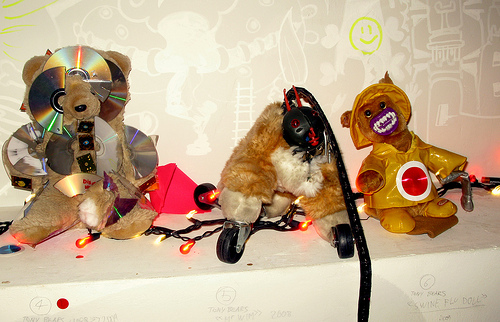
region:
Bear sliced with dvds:
[4, 50, 160, 242]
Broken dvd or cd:
[51, 170, 107, 197]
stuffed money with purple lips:
[341, 59, 478, 256]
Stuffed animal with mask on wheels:
[204, 79, 351, 276]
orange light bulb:
[178, 226, 199, 258]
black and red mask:
[278, 83, 329, 167]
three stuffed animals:
[12, 38, 487, 278]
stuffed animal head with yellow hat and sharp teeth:
[331, 67, 429, 149]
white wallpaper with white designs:
[148, 7, 347, 82]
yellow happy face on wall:
[346, 18, 393, 58]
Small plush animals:
[19, 38, 470, 255]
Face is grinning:
[360, 85, 405, 145]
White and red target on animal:
[396, 152, 434, 208]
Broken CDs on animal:
[38, 48, 161, 179]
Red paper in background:
[150, 160, 202, 220]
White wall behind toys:
[22, 10, 498, 93]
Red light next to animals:
[163, 220, 201, 260]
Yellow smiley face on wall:
[346, 12, 402, 64]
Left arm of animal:
[351, 159, 392, 203]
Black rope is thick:
[290, 76, 390, 315]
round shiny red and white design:
[391, 164, 430, 201]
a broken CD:
[18, 65, 79, 135]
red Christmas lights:
[76, 207, 343, 274]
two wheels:
[211, 202, 358, 269]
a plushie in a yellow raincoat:
[340, 80, 480, 241]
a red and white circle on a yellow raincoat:
[386, 160, 440, 204]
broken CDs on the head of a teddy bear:
[23, 46, 135, 132]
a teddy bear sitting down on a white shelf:
[9, 47, 178, 249]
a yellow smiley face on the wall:
[327, 12, 398, 62]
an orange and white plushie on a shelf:
[221, 95, 353, 234]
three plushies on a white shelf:
[12, 52, 489, 264]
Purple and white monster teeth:
[367, 108, 404, 138]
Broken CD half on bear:
[24, 65, 69, 135]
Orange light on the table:
[176, 234, 200, 256]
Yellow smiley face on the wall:
[339, 13, 394, 65]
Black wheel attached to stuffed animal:
[213, 211, 253, 268]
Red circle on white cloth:
[48, 291, 78, 313]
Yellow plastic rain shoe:
[385, 211, 418, 233]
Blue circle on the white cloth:
[0, 241, 24, 256]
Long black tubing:
[339, 182, 386, 319]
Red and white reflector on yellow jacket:
[394, 161, 436, 204]